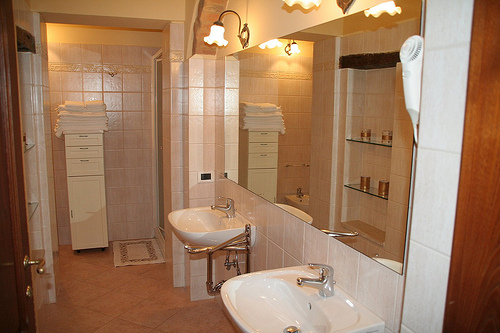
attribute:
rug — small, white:
[115, 235, 157, 265]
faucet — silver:
[209, 194, 233, 217]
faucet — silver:
[294, 261, 331, 296]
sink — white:
[164, 205, 256, 253]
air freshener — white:
[399, 34, 423, 146]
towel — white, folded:
[39, 87, 156, 154]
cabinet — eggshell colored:
[54, 94, 118, 252]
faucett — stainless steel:
[285, 249, 359, 316]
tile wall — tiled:
[116, 71, 146, 231]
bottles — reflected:
[333, 111, 405, 210]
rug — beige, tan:
[110, 239, 165, 269]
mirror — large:
[225, 0, 424, 274]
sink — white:
[219, 265, 386, 332]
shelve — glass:
[345, 136, 390, 147]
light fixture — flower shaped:
[203, 19, 228, 48]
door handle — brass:
[16, 238, 51, 280]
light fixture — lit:
[202, 7, 252, 54]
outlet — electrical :
[197, 170, 214, 181]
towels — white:
[49, 96, 113, 138]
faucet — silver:
[291, 255, 340, 297]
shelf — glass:
[345, 133, 391, 148]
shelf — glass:
[343, 174, 390, 201]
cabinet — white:
[59, 126, 112, 252]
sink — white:
[166, 198, 256, 250]